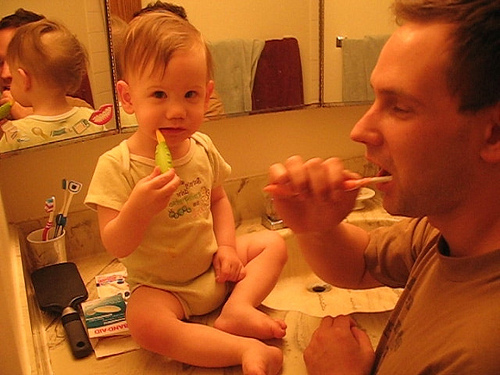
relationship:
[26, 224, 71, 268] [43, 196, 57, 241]
cup with toothbrush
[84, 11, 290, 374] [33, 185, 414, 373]
baby on counter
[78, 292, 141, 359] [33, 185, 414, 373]
box on counter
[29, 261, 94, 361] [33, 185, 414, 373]
brush on counter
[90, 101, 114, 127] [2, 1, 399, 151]
sticker on mirror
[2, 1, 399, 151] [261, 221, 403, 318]
mirror over sink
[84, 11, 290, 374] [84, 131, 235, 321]
baby in onesie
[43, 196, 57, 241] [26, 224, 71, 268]
toothbrush in cup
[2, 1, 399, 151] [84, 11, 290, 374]
mirror behind baby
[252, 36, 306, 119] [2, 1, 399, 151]
towel in mirror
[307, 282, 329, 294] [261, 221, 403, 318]
drain in sink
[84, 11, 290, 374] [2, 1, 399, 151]
baby in mirror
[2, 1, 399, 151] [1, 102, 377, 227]
mirror on wall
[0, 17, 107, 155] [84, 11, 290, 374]
reflection of baby